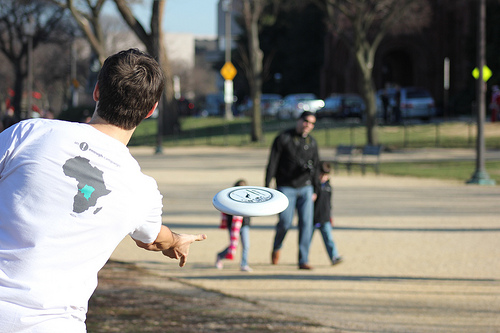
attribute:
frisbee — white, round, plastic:
[216, 181, 281, 218]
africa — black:
[60, 156, 105, 219]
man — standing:
[3, 43, 192, 332]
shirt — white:
[2, 121, 129, 320]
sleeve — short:
[142, 188, 156, 244]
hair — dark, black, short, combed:
[101, 58, 148, 119]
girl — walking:
[220, 184, 258, 271]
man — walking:
[269, 112, 311, 270]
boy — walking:
[317, 161, 341, 261]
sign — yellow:
[218, 60, 237, 82]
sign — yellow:
[471, 66, 492, 79]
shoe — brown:
[273, 251, 279, 265]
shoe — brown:
[299, 260, 315, 270]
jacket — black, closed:
[281, 138, 314, 187]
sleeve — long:
[262, 139, 282, 180]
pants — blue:
[279, 186, 310, 257]